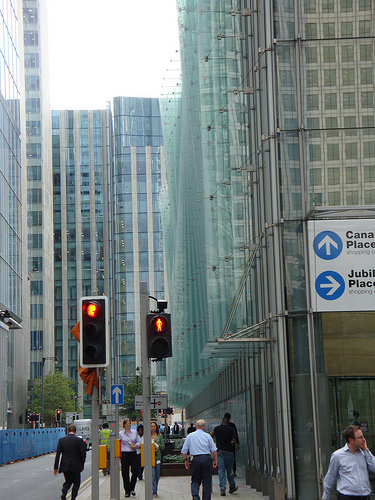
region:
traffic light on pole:
[73, 287, 115, 370]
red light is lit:
[85, 300, 97, 315]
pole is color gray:
[83, 366, 104, 498]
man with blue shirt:
[180, 413, 221, 494]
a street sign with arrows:
[304, 214, 373, 314]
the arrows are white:
[312, 221, 348, 304]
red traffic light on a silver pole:
[78, 291, 109, 497]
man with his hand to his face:
[320, 422, 373, 498]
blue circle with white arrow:
[312, 228, 342, 260]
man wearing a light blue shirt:
[181, 419, 218, 498]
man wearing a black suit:
[52, 421, 86, 498]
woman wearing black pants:
[115, 417, 141, 496]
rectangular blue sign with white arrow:
[108, 383, 125, 407]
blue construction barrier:
[0, 422, 66, 466]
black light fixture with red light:
[145, 310, 172, 361]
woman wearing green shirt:
[142, 421, 165, 497]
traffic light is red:
[73, 291, 113, 374]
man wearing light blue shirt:
[319, 422, 371, 499]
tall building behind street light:
[50, 100, 116, 420]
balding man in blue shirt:
[177, 415, 219, 498]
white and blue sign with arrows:
[302, 210, 373, 319]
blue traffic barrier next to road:
[1, 422, 72, 467]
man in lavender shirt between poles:
[115, 411, 141, 497]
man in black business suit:
[51, 420, 90, 499]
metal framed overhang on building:
[182, 212, 287, 368]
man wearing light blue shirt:
[183, 417, 217, 495]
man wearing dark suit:
[42, 417, 90, 489]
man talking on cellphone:
[325, 419, 363, 493]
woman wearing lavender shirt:
[115, 405, 140, 496]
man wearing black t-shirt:
[207, 406, 241, 490]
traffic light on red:
[66, 281, 111, 366]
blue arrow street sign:
[107, 381, 131, 408]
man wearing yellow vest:
[90, 413, 116, 467]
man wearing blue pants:
[182, 423, 225, 488]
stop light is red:
[81, 298, 107, 363]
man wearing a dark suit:
[52, 424, 86, 499]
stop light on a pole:
[90, 369, 100, 499]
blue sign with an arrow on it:
[111, 384, 122, 403]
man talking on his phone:
[318, 424, 373, 499]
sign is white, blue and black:
[306, 217, 373, 312]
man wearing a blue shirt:
[180, 416, 218, 498]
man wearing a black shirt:
[210, 413, 237, 496]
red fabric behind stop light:
[69, 317, 100, 395]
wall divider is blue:
[0, 425, 66, 465]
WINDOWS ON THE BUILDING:
[327, 69, 338, 87]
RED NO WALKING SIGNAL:
[151, 316, 164, 333]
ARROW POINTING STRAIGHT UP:
[314, 232, 340, 258]